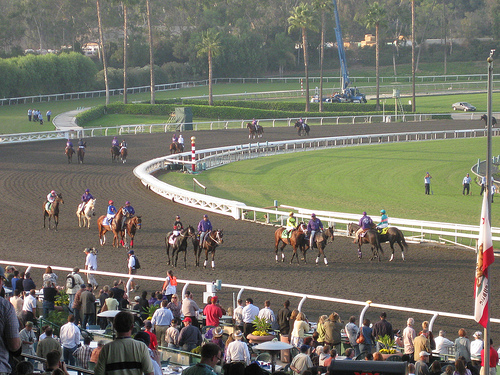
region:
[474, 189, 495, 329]
white and red flag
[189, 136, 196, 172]
red and white striped pole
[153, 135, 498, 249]
grassy section in the middle of track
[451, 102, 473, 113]
gold car parked near the track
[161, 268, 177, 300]
woman with bright orange vest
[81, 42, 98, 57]
white house with brown roof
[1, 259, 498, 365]
white fence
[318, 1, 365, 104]
blue work truck with long ladder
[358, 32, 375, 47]
large brown building in the background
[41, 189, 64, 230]
horse and jockey with pink helmet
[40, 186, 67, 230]
horse on a race track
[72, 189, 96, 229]
horse on a race track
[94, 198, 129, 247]
horse on a race track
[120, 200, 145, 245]
horse on a race track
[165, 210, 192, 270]
horse on a race track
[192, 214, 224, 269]
horse on a race track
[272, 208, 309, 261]
horse on a race track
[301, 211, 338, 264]
horse on a race track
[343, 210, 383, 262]
horse on a race track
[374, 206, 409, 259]
horse on a race track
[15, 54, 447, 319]
horses running outside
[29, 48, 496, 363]
horses running on a track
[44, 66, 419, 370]
people riding horses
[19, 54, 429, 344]
people riding race horses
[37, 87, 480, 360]
a person riding horses on a track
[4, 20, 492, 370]
a person riding a horse in a race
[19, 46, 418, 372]
a race track with horse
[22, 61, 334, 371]
race track with horses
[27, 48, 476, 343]
race track with racing horses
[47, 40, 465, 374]
race track with racing horse racing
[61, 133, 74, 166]
A person riding a horse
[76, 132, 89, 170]
A person riding a horse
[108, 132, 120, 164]
A person riding a horse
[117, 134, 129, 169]
A person riding a horse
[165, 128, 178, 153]
A person riding a horse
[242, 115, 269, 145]
A person riding a horse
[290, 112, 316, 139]
A person riding a horse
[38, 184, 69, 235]
A person riding a horse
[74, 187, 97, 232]
A person riding a horse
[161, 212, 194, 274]
A person riding a horse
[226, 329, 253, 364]
Man wearing white shirt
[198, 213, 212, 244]
Man wearing purple shirt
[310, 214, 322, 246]
Man wearing purple shirt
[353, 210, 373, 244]
Man wearing purple shirt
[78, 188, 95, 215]
Man wearing purple shirt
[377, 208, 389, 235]
Man wearing blue shirt and hat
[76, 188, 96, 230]
Man in purple shirt riding white horse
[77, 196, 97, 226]
White horse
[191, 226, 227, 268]
Brown horse with white bandanges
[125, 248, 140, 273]
Man wearing black backpack